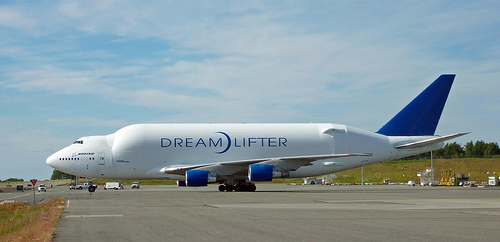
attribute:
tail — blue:
[372, 60, 460, 144]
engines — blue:
[245, 153, 280, 188]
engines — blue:
[179, 156, 209, 195]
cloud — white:
[8, 55, 199, 104]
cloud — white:
[9, 3, 419, 130]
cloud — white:
[413, 57, 499, 157]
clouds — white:
[228, 47, 298, 84]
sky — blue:
[115, 36, 151, 56]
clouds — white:
[94, 60, 170, 100]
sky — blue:
[97, 25, 164, 77]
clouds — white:
[1, 10, 486, 130]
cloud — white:
[13, 58, 137, 96]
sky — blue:
[1, 0, 496, 178]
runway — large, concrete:
[1, 182, 497, 239]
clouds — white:
[0, 2, 495, 176]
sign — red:
[28, 175, 40, 185]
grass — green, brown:
[2, 197, 67, 238]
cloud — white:
[161, 26, 347, 103]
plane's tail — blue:
[378, 73, 469, 162]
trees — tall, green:
[440, 139, 498, 157]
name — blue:
[157, 133, 295, 149]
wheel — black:
[227, 186, 241, 195]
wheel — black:
[85, 181, 95, 193]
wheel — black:
[217, 181, 225, 191]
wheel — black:
[222, 182, 235, 191]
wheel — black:
[246, 182, 256, 192]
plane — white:
[46, 70, 467, 197]